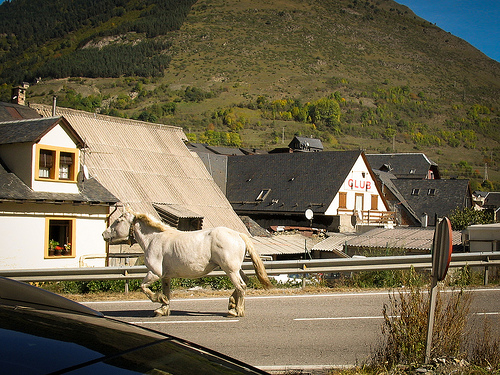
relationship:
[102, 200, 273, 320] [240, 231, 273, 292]
pony has a tail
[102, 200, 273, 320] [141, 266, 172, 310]
pony has leg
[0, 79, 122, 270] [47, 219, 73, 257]
building has window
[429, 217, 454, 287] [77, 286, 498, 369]
sign on road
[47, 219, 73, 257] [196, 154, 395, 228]
window on house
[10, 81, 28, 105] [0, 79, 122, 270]
chimney on building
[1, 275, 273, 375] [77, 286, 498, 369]
car on road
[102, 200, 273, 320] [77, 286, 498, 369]
pony on road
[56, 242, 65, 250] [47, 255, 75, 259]
plant on sill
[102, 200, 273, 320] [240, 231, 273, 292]
pony has tail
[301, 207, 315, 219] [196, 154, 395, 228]
dish on house